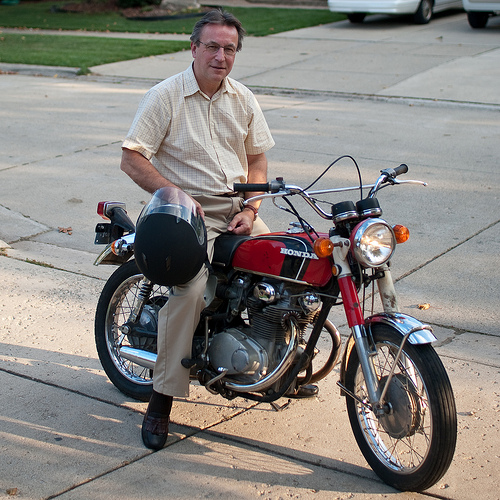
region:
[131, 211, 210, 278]
Man holding a black helmet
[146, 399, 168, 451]
Dress shoe on a man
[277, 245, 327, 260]
HONDA sign on a motorcycle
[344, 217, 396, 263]
Headlight on a motorcycle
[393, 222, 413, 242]
Orange turn signal on a motorcycle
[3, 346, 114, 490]
Shadow of a man on a motorcycle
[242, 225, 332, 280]
Red body of a motorcycle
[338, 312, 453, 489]
Front wheel of a motorcycle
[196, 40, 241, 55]
Glasses on a man's face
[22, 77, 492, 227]
Street behind a man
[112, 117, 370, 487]
a man in a bike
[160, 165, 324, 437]
a man in a bike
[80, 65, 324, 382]
a man in a bike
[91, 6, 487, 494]
man on a red and black motorcycle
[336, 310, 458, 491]
motorcycle wheel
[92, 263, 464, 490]
two motorcycle wheels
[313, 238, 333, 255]
orange headlight of a motorcycle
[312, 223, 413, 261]
two orange headlights on a motorcycle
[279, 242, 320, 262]
white text on a motorcycle reading Honda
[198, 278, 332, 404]
engine of a motorcycle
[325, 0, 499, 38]
two parked vehicles in a driveway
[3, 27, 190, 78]
strip of grass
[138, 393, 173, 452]
black shoes on a man's foot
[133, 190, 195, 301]
This man is holding a motorcycle helmet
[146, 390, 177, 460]
This man is wearing black dress shoes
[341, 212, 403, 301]
There is a bright headlight that is on this motorcycle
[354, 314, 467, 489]
There is a large black tire on this motorcycle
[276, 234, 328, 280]
This motorcycle has the brand of Honda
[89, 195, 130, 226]
There is a large tail light on this motorcycle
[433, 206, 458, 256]
The cement is a very light grey color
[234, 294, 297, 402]
This engine is a stainless steel color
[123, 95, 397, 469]
This photo was taken in the early morning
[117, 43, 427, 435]
This photo was taken in the state of Ohio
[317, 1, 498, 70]
two parked cars in a driveway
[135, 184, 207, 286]
black motorcycle helmet with clear face guard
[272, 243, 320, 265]
the word Honda printed on the motorcycle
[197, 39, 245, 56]
glasses on man's face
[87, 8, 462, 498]
man sitting on motorcycle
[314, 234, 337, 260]
small orange turn signal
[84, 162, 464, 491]
motorcycle is in drive way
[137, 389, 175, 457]
shoe is brown with tassels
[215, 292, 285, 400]
silver engine of motorcycle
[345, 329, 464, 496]
black front wheel has small tire